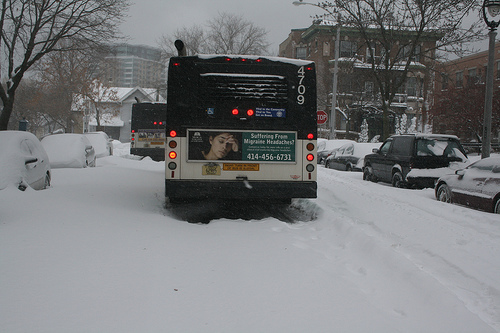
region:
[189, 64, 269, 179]
back of the bus is black and white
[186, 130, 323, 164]
ad on back of bus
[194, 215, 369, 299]
tracks in white snow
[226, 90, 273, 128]
red lights in back of bus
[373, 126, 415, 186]
black suv parked on street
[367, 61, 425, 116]
tree with dark branches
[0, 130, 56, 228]
car covered in snow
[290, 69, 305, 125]
numbers on back of bus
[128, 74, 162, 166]
bus in front of other bus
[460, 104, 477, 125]
brown building in distance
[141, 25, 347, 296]
bus driving on a snowy road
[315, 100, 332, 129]
stop sign at the corner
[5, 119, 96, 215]
vehicles buried in the snow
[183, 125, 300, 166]
sign for migraines on back of bus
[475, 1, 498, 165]
street light on the side of the road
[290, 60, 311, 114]
number of bus is 4709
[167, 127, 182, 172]
tail light on a bus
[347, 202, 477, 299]
tread in snow from tires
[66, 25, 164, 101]
tall apartment complex in the background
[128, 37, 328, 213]
two buses on a snow-covered road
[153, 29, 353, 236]
this is a bus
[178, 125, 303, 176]
a billboard on the back of the bus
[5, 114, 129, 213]
these cars are covered in snow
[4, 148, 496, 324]
the street is buried in snow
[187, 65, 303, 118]
this is an engine vent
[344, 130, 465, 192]
there isn't as much snow on this truck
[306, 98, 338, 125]
a red and white stop sign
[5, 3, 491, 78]
the sky is enveloped in fog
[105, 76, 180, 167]
this is another bus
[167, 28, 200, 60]
the dark exhaust pipe of a bus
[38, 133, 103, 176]
A car buried in snow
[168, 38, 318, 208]
The back end of a bus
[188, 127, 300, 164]
A sign on the back of a bus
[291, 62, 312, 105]
Numbers on the back of a bus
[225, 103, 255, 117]
Lights on the back of a bus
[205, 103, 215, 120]
Handicap tag on the back of a bus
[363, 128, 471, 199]
Black car with snow on it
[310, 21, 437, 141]
Building covered in snow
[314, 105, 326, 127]
Stop sign in the distance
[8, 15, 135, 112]
Trees with no leaves on them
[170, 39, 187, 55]
Exhaust on a bus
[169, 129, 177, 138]
Red light on a bus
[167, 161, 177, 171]
A light on a bus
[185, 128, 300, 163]
A banner on a bus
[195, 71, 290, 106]
The vent on a bus engine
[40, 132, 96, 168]
Car parked in snow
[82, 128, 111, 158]
Car covered in snow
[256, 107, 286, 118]
A blue sign on a bus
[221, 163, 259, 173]
Yellow license plate on a bus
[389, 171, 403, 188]
Rear left tire on an SUV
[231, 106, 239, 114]
the light is red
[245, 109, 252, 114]
the light is red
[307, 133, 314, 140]
the light is red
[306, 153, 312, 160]
the light is red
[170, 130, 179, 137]
the light is red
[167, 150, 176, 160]
the light is red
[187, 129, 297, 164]
sign on the bus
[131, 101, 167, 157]
back of a bus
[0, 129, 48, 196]
van covered in snow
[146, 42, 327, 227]
black and white passenger bus